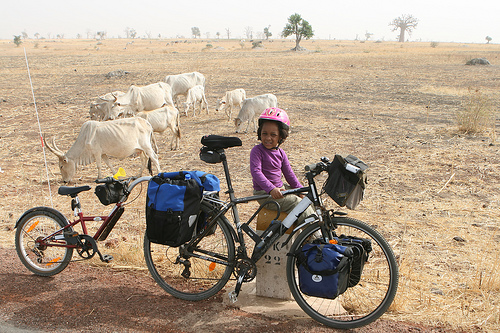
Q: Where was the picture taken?
A: It was taken at the plain.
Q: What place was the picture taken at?
A: It was taken at the plain.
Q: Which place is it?
A: It is a plain.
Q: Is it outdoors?
A: Yes, it is outdoors.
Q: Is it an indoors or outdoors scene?
A: It is outdoors.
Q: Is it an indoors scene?
A: No, it is outdoors.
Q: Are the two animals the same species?
A: No, they are goats and cows.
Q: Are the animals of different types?
A: Yes, they are goats and cows.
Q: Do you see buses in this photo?
A: No, there are no buses.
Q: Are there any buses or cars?
A: No, there are no buses or cars.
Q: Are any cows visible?
A: Yes, there is a cow.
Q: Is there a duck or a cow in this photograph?
A: Yes, there is a cow.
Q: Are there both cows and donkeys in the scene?
A: No, there is a cow but no donkeys.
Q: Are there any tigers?
A: No, there are no tigers.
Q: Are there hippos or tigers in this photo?
A: No, there are no tigers or hippos.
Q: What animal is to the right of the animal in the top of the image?
A: The animal is a cow.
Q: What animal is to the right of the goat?
A: The animal is a cow.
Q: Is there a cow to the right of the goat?
A: Yes, there is a cow to the right of the goat.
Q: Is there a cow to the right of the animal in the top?
A: Yes, there is a cow to the right of the goat.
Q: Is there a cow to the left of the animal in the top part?
A: No, the cow is to the right of the goat.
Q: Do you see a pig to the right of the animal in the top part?
A: No, there is a cow to the right of the goat.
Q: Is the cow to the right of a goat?
A: Yes, the cow is to the right of a goat.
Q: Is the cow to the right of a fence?
A: No, the cow is to the right of a goat.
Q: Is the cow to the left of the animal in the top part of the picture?
A: No, the cow is to the right of the goat.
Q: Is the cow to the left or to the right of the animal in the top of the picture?
A: The cow is to the right of the goat.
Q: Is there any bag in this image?
A: Yes, there is a bag.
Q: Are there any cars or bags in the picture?
A: Yes, there is a bag.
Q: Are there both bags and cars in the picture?
A: No, there is a bag but no cars.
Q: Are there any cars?
A: No, there are no cars.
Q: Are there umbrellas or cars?
A: No, there are no cars or umbrellas.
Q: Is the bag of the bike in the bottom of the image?
A: Yes, the bag is in the bottom of the image.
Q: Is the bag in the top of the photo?
A: No, the bag is in the bottom of the image.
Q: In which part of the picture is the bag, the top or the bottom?
A: The bag is in the bottom of the image.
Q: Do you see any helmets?
A: Yes, there is a helmet.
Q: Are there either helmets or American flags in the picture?
A: Yes, there is a helmet.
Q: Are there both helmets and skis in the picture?
A: No, there is a helmet but no skis.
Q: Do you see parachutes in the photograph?
A: No, there are no parachutes.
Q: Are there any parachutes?
A: No, there are no parachutes.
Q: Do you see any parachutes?
A: No, there are no parachutes.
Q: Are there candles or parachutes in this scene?
A: No, there are no parachutes or candles.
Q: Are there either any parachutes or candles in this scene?
A: No, there are no parachutes or candles.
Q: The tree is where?
A: The tree is in the plain.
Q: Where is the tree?
A: The tree is in the plain.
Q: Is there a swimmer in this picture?
A: No, there are no swimmers.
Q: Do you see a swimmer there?
A: No, there are no swimmers.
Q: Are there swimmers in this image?
A: No, there are no swimmers.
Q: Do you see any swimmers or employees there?
A: No, there are no swimmers or employees.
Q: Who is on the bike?
A: The girl is on the bike.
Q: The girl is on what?
A: The girl is on the bike.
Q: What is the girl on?
A: The girl is on the bike.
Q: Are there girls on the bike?
A: Yes, there is a girl on the bike.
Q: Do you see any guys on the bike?
A: No, there is a girl on the bike.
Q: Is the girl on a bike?
A: Yes, the girl is on a bike.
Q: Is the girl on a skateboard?
A: No, the girl is on a bike.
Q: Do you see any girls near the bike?
A: Yes, there is a girl near the bike.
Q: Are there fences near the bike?
A: No, there is a girl near the bike.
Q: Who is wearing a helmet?
A: The girl is wearing a helmet.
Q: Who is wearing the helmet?
A: The girl is wearing a helmet.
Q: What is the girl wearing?
A: The girl is wearing a helmet.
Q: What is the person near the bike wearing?
A: The girl is wearing a helmet.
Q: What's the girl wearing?
A: The girl is wearing a helmet.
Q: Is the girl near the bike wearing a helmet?
A: Yes, the girl is wearing a helmet.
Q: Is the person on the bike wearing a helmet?
A: Yes, the girl is wearing a helmet.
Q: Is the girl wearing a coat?
A: No, the girl is wearing a helmet.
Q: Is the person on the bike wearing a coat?
A: No, the girl is wearing a helmet.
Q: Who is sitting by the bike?
A: The girl is sitting by the bike.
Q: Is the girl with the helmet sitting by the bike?
A: Yes, the girl is sitting by the bike.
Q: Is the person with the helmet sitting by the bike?
A: Yes, the girl is sitting by the bike.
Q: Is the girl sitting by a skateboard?
A: No, the girl is sitting by the bike.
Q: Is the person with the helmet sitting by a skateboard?
A: No, the girl is sitting by the bike.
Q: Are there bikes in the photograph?
A: Yes, there is a bike.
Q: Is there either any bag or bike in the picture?
A: Yes, there is a bike.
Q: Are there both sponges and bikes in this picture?
A: No, there is a bike but no sponges.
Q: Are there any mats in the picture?
A: No, there are no mats.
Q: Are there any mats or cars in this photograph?
A: No, there are no mats or cars.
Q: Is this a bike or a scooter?
A: This is a bike.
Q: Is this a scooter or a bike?
A: This is a bike.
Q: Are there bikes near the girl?
A: Yes, there is a bike near the girl.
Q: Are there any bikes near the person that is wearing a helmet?
A: Yes, there is a bike near the girl.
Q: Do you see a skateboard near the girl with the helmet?
A: No, there is a bike near the girl.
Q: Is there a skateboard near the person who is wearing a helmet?
A: No, there is a bike near the girl.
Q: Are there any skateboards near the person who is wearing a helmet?
A: No, there is a bike near the girl.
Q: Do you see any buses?
A: No, there are no buses.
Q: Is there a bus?
A: No, there are no buses.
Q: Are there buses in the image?
A: No, there are no buses.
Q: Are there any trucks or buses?
A: No, there are no buses or trucks.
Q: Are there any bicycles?
A: Yes, there is a bicycle.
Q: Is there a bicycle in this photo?
A: Yes, there is a bicycle.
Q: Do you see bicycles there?
A: Yes, there is a bicycle.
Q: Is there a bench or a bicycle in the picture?
A: Yes, there is a bicycle.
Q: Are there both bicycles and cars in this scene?
A: No, there is a bicycle but no cars.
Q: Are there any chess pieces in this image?
A: No, there are no chess pieces.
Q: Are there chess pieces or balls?
A: No, there are no chess pieces or balls.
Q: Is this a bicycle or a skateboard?
A: This is a bicycle.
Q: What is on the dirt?
A: The bicycle is on the dirt.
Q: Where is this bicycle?
A: The bicycle is on the dirt.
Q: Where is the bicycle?
A: The bicycle is on the dirt.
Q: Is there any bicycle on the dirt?
A: Yes, there is a bicycle on the dirt.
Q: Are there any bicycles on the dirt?
A: Yes, there is a bicycle on the dirt.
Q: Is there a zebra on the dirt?
A: No, there is a bicycle on the dirt.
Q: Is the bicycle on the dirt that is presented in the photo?
A: Yes, the bicycle is on the dirt.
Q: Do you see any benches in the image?
A: No, there are no benches.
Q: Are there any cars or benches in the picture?
A: No, there are no benches or cars.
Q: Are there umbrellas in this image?
A: No, there are no umbrellas.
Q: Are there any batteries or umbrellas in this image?
A: No, there are no umbrellas or batteries.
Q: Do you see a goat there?
A: Yes, there is a goat.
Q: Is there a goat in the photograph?
A: Yes, there is a goat.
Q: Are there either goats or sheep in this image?
A: Yes, there is a goat.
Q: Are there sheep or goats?
A: Yes, there is a goat.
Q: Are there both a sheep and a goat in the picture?
A: No, there is a goat but no sheep.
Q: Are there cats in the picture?
A: No, there are no cats.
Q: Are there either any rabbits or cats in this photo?
A: No, there are no cats or rabbits.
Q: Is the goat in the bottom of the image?
A: No, the goat is in the top of the image.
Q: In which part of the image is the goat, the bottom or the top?
A: The goat is in the top of the image.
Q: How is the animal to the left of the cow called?
A: The animal is a goat.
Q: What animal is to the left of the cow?
A: The animal is a goat.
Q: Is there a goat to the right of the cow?
A: No, the goat is to the left of the cow.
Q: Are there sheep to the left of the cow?
A: No, there is a goat to the left of the cow.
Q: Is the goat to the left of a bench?
A: No, the goat is to the left of a cow.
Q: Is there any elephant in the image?
A: No, there are no elephants.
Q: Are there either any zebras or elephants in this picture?
A: No, there are no elephants or zebras.